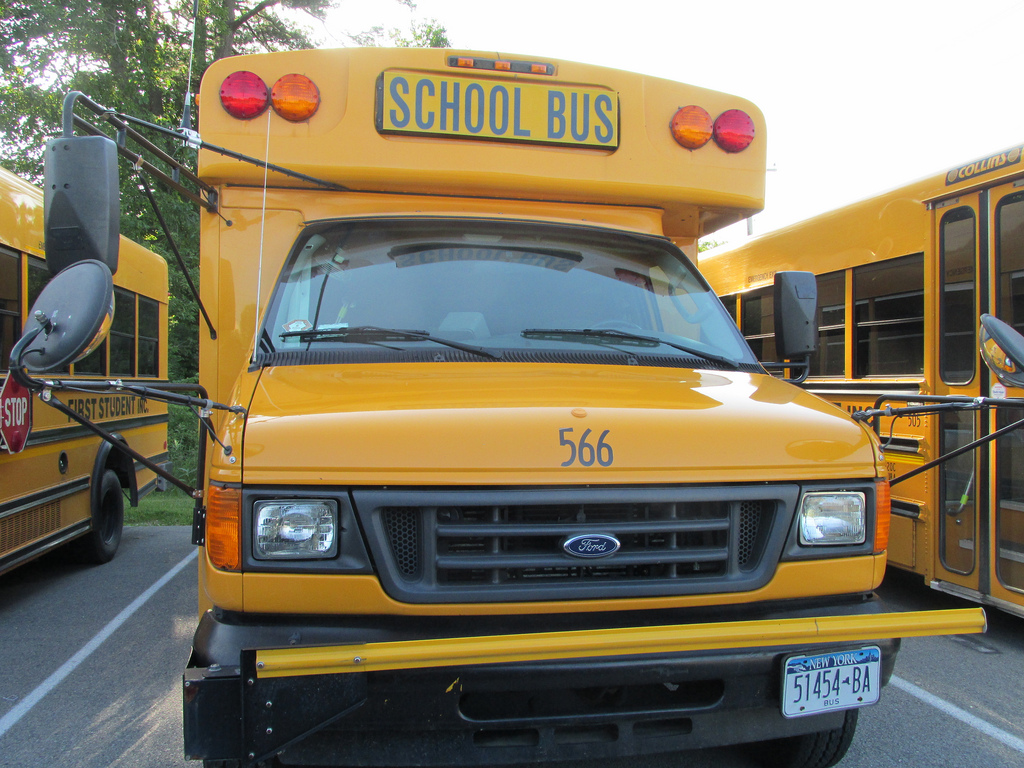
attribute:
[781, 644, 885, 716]
license plate — white and blue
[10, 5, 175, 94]
green leaves — on the tree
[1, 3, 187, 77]
green leaves — on the tree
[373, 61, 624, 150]
sign — school bus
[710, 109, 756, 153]
light — red, circular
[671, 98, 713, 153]
light — circular, orange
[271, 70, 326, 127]
light — large, circular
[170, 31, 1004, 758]
bus — yellow, parked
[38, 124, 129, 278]
mirror — large, rectangular, black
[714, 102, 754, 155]
light — orange, circular, red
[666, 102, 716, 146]
light — circular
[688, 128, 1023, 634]
bus — yellow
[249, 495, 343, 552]
headlight — clear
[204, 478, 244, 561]
light — orange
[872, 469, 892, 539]
light — orange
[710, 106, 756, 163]
light — red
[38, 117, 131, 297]
mirror — rectangular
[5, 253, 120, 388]
mirror — round